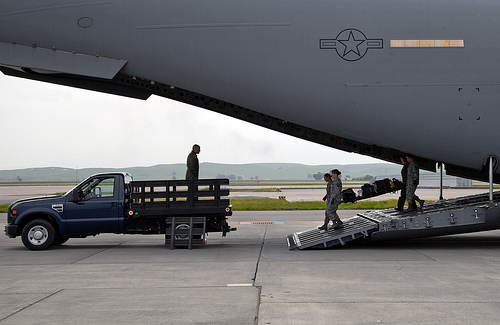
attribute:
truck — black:
[9, 168, 240, 253]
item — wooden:
[164, 215, 206, 248]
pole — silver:
[485, 161, 497, 198]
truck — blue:
[73, 140, 270, 267]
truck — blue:
[1, 145, 252, 251]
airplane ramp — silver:
[286, 215, 486, 250]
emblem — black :
[316, 27, 386, 62]